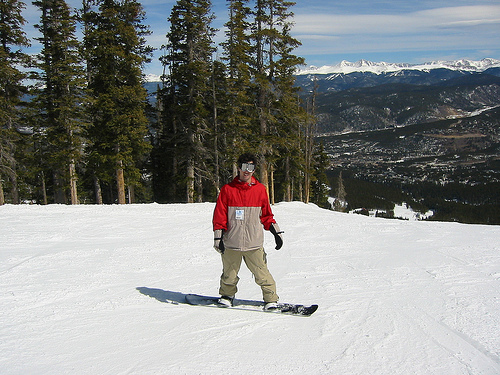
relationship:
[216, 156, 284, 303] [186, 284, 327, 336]
man on snowboard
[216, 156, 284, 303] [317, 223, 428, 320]
man on hill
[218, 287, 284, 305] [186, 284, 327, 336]
feet on snowboard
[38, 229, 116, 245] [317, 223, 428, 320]
ground on hill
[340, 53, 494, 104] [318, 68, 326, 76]
mountains have snow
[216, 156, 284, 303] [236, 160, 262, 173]
man in goggles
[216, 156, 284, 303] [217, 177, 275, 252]
man in jacket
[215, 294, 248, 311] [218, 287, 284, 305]
straps on feet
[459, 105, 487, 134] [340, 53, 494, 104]
slants on mountains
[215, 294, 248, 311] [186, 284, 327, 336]
straps on snowboard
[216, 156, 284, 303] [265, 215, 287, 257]
man in gloves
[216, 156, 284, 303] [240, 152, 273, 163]
man has hair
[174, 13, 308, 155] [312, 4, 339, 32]
trees in back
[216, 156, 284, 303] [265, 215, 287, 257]
man wears gloves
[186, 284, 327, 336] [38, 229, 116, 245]
snowboard on ground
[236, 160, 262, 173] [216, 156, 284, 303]
goggles on man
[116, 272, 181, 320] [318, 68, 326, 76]
shadow on snow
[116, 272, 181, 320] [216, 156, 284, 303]
shadow of man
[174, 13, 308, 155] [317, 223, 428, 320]
trees on hill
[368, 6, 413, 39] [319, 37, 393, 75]
clouds in sky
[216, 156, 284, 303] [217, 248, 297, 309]
man in pants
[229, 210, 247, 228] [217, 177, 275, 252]
lift ticket on jacket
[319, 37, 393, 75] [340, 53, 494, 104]
sky over mountains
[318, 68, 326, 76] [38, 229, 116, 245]
snow on ground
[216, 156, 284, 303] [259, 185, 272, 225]
man has arm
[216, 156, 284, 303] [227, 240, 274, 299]
man has legs